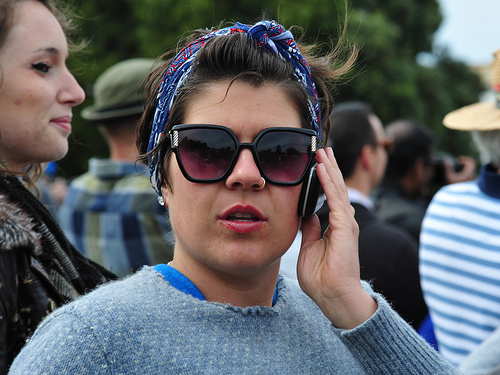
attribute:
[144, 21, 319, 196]
headband — blue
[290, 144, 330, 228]
phone — cell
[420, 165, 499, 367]
shirt — striped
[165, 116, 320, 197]
sunglasses — black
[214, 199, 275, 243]
lipstick — pink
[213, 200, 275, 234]
mouth — open, her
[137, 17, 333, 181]
headband — blue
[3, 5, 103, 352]
woman — smiling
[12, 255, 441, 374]
sweater — blue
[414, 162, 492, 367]
shirt — blue, striped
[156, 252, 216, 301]
tshirt — blue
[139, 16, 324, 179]
bandana — red, white, blue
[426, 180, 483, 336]
shirt — blue, white, striped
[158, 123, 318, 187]
glasses — tinted 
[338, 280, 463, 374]
sleeve — blue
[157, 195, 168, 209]
earring — small, diamond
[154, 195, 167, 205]
earring — diamond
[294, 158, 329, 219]
cell phone — small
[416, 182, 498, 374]
striped shirt — blue, white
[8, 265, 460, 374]
sweater — blue, thick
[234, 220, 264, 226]
lipstick — red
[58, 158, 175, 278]
shirt — blue, plaid